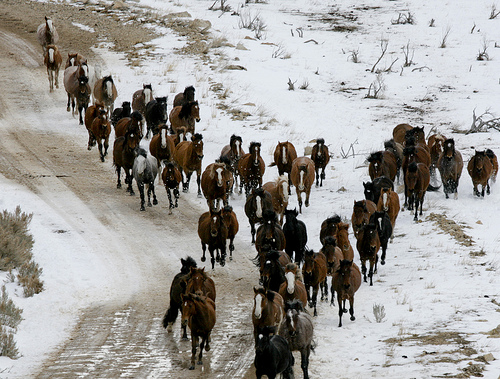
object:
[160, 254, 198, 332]
horse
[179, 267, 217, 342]
horse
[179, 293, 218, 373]
horse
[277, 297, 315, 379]
horse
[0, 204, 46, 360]
bushes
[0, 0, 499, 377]
snow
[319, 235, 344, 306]
horse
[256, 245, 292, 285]
horse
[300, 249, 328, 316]
horse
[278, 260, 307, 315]
horse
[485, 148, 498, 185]
horse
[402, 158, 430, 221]
horse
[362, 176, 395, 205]
horse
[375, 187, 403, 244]
horse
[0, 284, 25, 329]
grass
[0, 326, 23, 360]
grass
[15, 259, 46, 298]
grass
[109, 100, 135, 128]
horse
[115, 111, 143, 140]
horse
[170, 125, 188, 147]
horse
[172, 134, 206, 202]
horse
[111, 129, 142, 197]
horse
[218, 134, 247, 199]
horse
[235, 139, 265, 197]
horse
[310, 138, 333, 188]
horse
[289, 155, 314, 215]
horse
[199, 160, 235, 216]
horse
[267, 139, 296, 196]
horse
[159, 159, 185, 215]
horse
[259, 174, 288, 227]
horse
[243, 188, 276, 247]
horse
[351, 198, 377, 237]
horse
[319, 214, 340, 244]
horse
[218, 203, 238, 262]
horse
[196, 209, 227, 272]
horse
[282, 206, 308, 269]
horse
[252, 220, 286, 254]
horse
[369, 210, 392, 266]
horse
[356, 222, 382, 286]
horse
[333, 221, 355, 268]
horse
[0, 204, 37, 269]
grass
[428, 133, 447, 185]
horse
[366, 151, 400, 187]
horse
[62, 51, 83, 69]
horse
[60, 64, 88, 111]
horse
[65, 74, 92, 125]
horse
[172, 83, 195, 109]
horse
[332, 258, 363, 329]
horse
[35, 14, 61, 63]
horse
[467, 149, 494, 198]
horse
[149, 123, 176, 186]
horse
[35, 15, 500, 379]
herd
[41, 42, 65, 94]
horse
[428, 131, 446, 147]
horse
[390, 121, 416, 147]
horse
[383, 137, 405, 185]
horse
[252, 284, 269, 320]
head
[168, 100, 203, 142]
horse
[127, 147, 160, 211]
grey horse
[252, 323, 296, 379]
horse